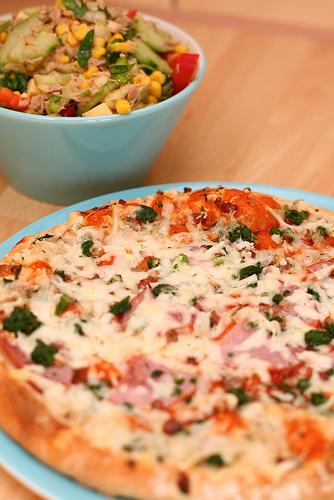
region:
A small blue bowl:
[1, 7, 208, 205]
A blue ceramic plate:
[0, 181, 330, 499]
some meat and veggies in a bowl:
[0, 4, 200, 117]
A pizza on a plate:
[0, 185, 331, 498]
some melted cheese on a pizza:
[0, 191, 333, 469]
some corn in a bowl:
[2, 21, 164, 114]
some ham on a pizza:
[0, 244, 330, 412]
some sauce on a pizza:
[27, 189, 331, 459]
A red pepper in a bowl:
[164, 49, 196, 90]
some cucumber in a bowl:
[0, 14, 173, 104]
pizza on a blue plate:
[1, 180, 331, 498]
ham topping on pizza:
[20, 269, 322, 417]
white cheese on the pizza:
[27, 226, 322, 478]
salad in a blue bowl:
[0, 3, 209, 180]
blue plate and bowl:
[1, 3, 326, 496]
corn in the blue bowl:
[5, 9, 187, 117]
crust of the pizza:
[2, 187, 332, 490]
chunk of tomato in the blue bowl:
[151, 50, 192, 86]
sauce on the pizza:
[85, 189, 291, 247]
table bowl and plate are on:
[2, 1, 324, 232]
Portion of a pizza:
[11, 232, 113, 355]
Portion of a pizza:
[33, 342, 134, 451]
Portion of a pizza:
[133, 200, 255, 313]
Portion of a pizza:
[232, 179, 313, 313]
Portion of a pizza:
[175, 370, 260, 480]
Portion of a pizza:
[24, 329, 206, 488]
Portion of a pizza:
[72, 369, 262, 496]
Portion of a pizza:
[234, 377, 321, 472]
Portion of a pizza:
[178, 318, 306, 474]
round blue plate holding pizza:
[0, 176, 331, 499]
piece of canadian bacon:
[219, 315, 289, 378]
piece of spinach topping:
[235, 260, 262, 283]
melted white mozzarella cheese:
[3, 192, 332, 476]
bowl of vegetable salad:
[1, 1, 201, 211]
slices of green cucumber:
[1, 2, 55, 66]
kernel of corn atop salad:
[112, 96, 132, 117]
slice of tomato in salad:
[167, 51, 202, 96]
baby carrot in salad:
[0, 85, 35, 112]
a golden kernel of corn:
[114, 94, 131, 113]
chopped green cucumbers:
[9, 23, 53, 57]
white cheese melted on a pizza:
[175, 264, 217, 294]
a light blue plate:
[0, 452, 51, 485]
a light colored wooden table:
[212, 34, 328, 167]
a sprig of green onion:
[105, 296, 138, 316]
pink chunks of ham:
[124, 357, 163, 379]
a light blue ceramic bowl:
[2, 112, 179, 186]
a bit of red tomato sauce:
[191, 201, 211, 226]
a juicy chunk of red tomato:
[171, 53, 192, 85]